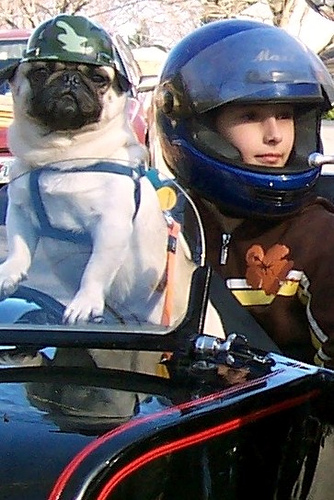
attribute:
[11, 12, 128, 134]
helmet — green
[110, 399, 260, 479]
stripe — red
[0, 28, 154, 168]
car — red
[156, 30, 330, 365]
girl — young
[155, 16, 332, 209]
helmet — blue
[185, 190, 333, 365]
jacket — brown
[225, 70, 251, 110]
helmet — blue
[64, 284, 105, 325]
paw — white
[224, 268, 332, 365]
stripe — white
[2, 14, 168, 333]
white dog — small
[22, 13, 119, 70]
hat — camo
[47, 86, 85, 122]
mouth — droopy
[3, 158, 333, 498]
vehicle — black, bright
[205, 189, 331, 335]
brown jacket — child's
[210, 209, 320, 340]
sweater — striped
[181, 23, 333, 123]
shield — face, clear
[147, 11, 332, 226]
helmet — blue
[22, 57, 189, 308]
dog — light grey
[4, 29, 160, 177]
car — red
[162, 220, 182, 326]
leash — orange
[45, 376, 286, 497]
stripe — red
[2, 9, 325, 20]
trees — bright, backyard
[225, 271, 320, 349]
stripe — yellow, white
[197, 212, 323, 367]
jacket — brown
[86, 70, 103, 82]
eye — black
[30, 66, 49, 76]
eye — black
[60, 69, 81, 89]
nose — black